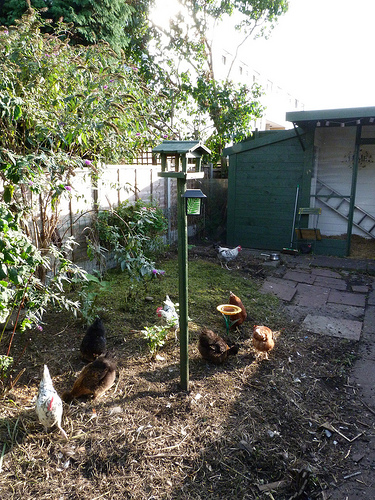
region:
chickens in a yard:
[23, 241, 313, 419]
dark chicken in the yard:
[192, 322, 233, 369]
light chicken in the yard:
[210, 235, 240, 271]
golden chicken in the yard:
[249, 325, 284, 365]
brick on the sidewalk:
[275, 274, 361, 331]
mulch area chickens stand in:
[9, 354, 313, 498]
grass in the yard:
[115, 262, 256, 315]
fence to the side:
[13, 155, 219, 260]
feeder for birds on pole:
[151, 131, 217, 401]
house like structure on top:
[153, 134, 213, 176]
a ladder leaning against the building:
[314, 179, 374, 237]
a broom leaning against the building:
[281, 183, 303, 254]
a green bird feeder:
[152, 134, 211, 393]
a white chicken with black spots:
[35, 362, 69, 442]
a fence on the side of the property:
[0, 158, 212, 298]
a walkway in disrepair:
[259, 258, 374, 340]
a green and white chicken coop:
[220, 100, 373, 261]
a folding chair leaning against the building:
[292, 204, 324, 255]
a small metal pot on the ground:
[258, 250, 282, 262]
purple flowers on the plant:
[150, 265, 168, 279]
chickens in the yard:
[12, 279, 290, 440]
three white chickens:
[26, 239, 247, 434]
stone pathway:
[264, 263, 374, 493]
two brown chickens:
[225, 282, 282, 358]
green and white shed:
[214, 105, 374, 256]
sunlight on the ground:
[14, 319, 269, 488]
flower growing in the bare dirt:
[135, 318, 170, 356]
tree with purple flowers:
[1, 42, 157, 445]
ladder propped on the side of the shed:
[312, 175, 374, 243]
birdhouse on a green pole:
[156, 138, 209, 392]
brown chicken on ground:
[58, 352, 124, 409]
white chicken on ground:
[28, 361, 73, 449]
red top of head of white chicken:
[46, 393, 56, 416]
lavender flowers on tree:
[57, 153, 95, 195]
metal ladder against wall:
[316, 177, 373, 247]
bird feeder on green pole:
[151, 132, 213, 183]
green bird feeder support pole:
[175, 178, 199, 393]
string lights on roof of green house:
[293, 118, 373, 131]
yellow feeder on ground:
[214, 300, 244, 328]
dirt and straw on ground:
[139, 410, 218, 477]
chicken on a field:
[23, 374, 77, 436]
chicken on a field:
[60, 355, 130, 419]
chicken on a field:
[75, 316, 131, 364]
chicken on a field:
[144, 302, 184, 346]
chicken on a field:
[185, 309, 248, 378]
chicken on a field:
[243, 325, 294, 366]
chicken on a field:
[213, 289, 262, 327]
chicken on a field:
[206, 227, 265, 278]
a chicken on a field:
[18, 345, 79, 457]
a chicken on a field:
[68, 337, 119, 412]